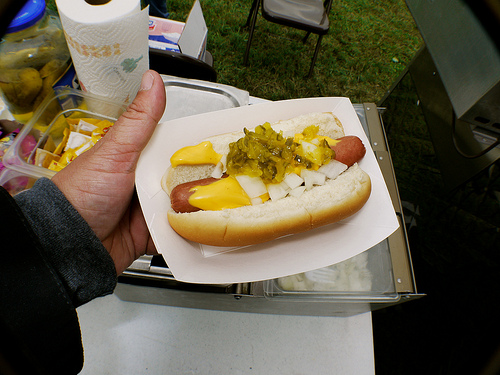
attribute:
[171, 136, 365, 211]
hot dog — brown, long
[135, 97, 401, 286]
plate — paper, cardboard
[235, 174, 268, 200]
onion — white', chopped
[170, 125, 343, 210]
mustard — yellow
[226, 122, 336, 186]
relish — green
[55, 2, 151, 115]
paper towel — printed, white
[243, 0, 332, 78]
chair — brown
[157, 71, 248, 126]
tray — metal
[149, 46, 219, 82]
chair — brown